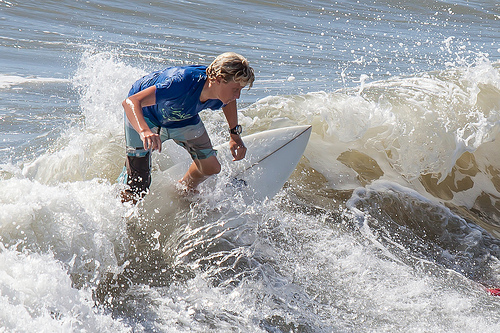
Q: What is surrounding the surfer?
A: Waves.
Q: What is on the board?
A: The person.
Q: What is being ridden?
A: The wave.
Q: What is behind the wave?
A: Calm water.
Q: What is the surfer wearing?
A: Shorts.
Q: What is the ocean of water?
A: Brown.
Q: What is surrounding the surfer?
A: The waves.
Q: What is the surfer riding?
A: The white surfboard.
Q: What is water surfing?
A: The man.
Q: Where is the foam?
A: In the water.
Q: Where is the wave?
A: In the water.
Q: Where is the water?
A: In the ocean.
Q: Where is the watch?
A: On the surfer.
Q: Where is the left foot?
A: On the surfboard.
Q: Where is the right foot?
A: On the surfboard.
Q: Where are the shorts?
A: On the man.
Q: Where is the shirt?
A: On the man.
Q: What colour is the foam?
A: White.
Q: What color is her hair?
A: Blonde.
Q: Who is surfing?
A: A woman.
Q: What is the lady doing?
A: Surfing.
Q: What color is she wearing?
A: Blue.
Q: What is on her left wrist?
A: A watch.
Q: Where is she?
A: The ocean.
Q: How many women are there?
A: One.